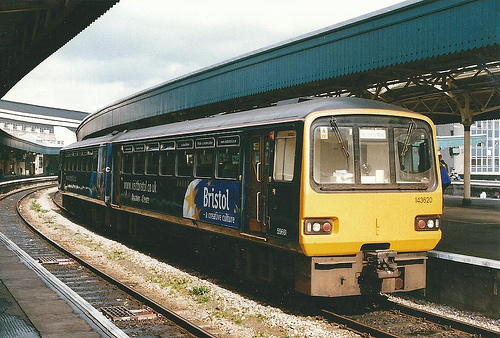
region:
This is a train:
[52, 88, 470, 315]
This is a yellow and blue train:
[4, 89, 482, 312]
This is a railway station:
[3, 1, 499, 335]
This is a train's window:
[271, 124, 299, 180]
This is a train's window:
[213, 146, 244, 178]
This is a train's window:
[194, 145, 217, 180]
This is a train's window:
[177, 143, 195, 178]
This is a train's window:
[159, 147, 179, 181]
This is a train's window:
[143, 148, 160, 175]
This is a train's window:
[131, 151, 144, 178]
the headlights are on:
[275, 205, 457, 248]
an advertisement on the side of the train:
[106, 164, 250, 247]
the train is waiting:
[26, 101, 458, 310]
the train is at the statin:
[143, 66, 488, 323]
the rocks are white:
[154, 267, 311, 329]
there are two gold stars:
[177, 175, 208, 220]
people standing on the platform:
[423, 144, 461, 196]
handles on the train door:
[240, 154, 263, 222]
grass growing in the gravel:
[144, 267, 259, 329]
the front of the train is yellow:
[276, 91, 463, 273]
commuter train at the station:
[38, 110, 465, 297]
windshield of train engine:
[298, 101, 434, 203]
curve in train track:
[3, 164, 128, 336]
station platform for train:
[328, 87, 498, 269]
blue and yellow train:
[111, 122, 457, 258]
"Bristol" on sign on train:
[194, 177, 243, 228]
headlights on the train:
[304, 215, 441, 234]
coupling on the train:
[355, 237, 409, 306]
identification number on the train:
[404, 188, 442, 215]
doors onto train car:
[236, 129, 283, 239]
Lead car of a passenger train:
[126, 85, 446, 305]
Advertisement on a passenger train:
[110, 171, 244, 231]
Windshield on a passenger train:
[308, 103, 438, 196]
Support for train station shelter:
[459, 117, 476, 214]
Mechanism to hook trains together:
[360, 241, 401, 296]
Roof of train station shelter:
[92, 45, 452, 83]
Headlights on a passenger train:
[301, 205, 441, 241]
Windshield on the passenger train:
[305, 112, 442, 197]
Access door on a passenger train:
[241, 118, 278, 243]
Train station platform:
[447, 203, 499, 249]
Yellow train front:
[283, 100, 452, 283]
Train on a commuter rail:
[127, 143, 464, 324]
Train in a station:
[108, 122, 497, 304]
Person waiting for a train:
[438, 151, 459, 201]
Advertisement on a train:
[117, 171, 258, 233]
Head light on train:
[302, 218, 344, 235]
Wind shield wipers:
[396, 127, 416, 163]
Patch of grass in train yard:
[60, 218, 132, 276]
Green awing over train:
[207, 23, 433, 89]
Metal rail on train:
[303, 257, 436, 293]